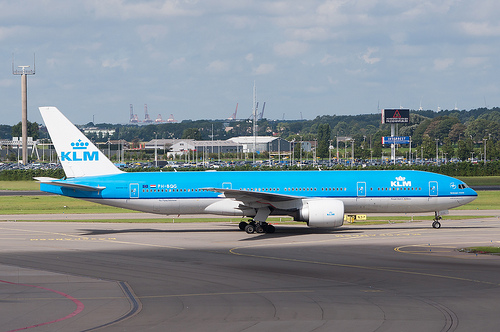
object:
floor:
[353, 238, 395, 267]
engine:
[299, 199, 345, 228]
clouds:
[1, 1, 498, 126]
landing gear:
[433, 222, 441, 229]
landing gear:
[256, 225, 265, 233]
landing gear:
[245, 225, 255, 234]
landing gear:
[239, 221, 249, 230]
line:
[235, 253, 500, 287]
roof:
[226, 136, 289, 144]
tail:
[38, 106, 125, 178]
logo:
[60, 139, 99, 162]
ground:
[0, 210, 497, 332]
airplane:
[33, 105, 479, 234]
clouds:
[455, 18, 494, 40]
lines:
[28, 226, 119, 253]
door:
[357, 182, 367, 196]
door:
[429, 181, 439, 197]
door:
[129, 183, 139, 198]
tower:
[10, 52, 36, 165]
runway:
[6, 205, 483, 327]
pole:
[21, 74, 28, 163]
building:
[226, 136, 295, 152]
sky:
[0, 1, 481, 128]